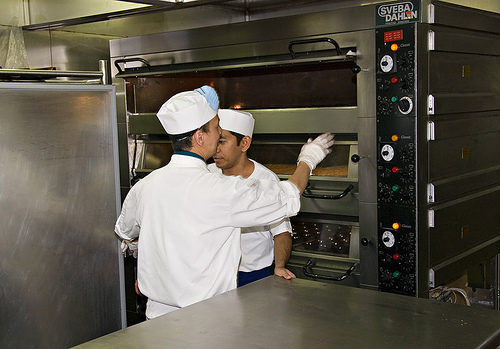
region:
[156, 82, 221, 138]
white chefs hat on head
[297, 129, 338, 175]
white gloves on hand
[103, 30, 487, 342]
stainless steel appliance in restaruant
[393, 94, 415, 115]
control knob on front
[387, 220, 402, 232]
amber colored light on appliance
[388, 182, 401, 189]
green light on front of appliance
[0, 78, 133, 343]
stainless steel door on appliance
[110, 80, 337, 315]
person wearing white with hat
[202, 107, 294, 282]
person wearing white and a hat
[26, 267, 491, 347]
stainless steel counter top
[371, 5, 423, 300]
Knobs on a oven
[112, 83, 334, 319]
A baker checking the oven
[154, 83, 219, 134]
A white bakers hat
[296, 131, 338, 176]
A white bakers glove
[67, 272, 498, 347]
A large metal bakers table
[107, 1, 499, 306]
Large multiple bakers ovens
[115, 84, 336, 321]
Two bakers on the job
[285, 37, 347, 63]
A black metal oven handle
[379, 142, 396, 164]
Temperature gauge on an oven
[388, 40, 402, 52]
A light on a bakers oven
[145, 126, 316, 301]
These are two chefs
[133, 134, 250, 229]
These are two men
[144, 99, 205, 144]
This is a hat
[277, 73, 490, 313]
This is a oven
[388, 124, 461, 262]
The oven is very large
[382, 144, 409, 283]
This is a knob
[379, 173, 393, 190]
This is a green button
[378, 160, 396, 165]
This is a red button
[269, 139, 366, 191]
This is a glove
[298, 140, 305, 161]
The glove is white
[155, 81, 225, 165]
Man wearing a white hat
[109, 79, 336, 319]
Two men standing by an oven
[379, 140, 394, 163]
White knob on an oven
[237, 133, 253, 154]
Left ear of a man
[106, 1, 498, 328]
Large silver baking oven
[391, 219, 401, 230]
Yellow light on an oven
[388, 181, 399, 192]
Green light on an oven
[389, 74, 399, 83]
Red light on an oven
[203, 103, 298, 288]
Man resting his hand on table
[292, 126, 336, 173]
White glove on mans right hand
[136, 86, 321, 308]
Two people talking in the kitchen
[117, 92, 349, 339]
Two chefs talking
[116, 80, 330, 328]
Two people wearing white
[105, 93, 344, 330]
Cook placing hands on oven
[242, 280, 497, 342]
Stainless table for food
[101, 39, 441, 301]
Large over behind two chefs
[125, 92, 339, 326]
Cook have blue on hat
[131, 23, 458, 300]
Over have 4 types of controls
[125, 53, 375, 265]
Oven have 3 windows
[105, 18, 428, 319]
Man have white gloves